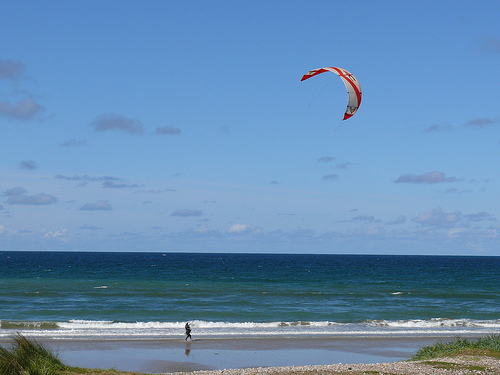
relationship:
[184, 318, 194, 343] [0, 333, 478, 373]
person walking on beach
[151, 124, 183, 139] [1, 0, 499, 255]
cloud in sky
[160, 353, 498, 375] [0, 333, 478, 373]
gravel near beach